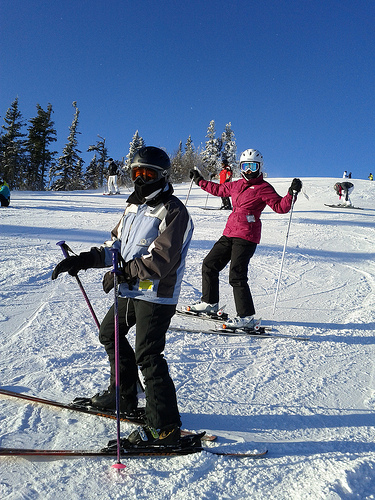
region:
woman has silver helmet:
[236, 145, 270, 175]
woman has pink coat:
[210, 161, 264, 233]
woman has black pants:
[207, 234, 262, 305]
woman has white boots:
[187, 291, 275, 343]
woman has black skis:
[162, 301, 275, 343]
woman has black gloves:
[178, 160, 314, 200]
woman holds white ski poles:
[253, 201, 314, 321]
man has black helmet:
[123, 151, 168, 191]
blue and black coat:
[97, 203, 180, 301]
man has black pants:
[94, 302, 181, 433]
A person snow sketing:
[203, 156, 278, 319]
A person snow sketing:
[90, 230, 211, 453]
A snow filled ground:
[241, 458, 344, 493]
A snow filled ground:
[107, 468, 213, 499]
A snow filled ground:
[12, 468, 78, 499]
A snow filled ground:
[258, 368, 341, 456]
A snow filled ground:
[322, 452, 373, 494]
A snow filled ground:
[15, 321, 69, 381]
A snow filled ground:
[7, 236, 45, 305]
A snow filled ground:
[280, 247, 329, 281]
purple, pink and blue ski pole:
[110, 244, 123, 473]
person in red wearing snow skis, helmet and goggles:
[174, 145, 303, 338]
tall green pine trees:
[3, 98, 88, 191]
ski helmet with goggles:
[129, 145, 171, 195]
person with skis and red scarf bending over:
[324, 181, 368, 209]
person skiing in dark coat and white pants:
[101, 155, 131, 196]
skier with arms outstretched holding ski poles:
[185, 147, 306, 214]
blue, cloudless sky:
[3, 2, 368, 174]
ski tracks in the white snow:
[185, 252, 373, 408]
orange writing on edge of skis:
[138, 450, 178, 458]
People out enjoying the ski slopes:
[29, 87, 364, 460]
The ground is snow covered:
[282, 234, 361, 361]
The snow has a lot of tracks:
[178, 320, 359, 473]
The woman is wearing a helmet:
[231, 143, 271, 163]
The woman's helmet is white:
[231, 142, 266, 168]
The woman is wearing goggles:
[229, 156, 270, 176]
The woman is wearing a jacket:
[190, 170, 306, 249]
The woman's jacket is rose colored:
[200, 171, 301, 253]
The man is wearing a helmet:
[111, 136, 177, 182]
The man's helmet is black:
[121, 138, 182, 178]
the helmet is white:
[231, 138, 277, 199]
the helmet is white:
[228, 142, 266, 183]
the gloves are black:
[38, 247, 163, 320]